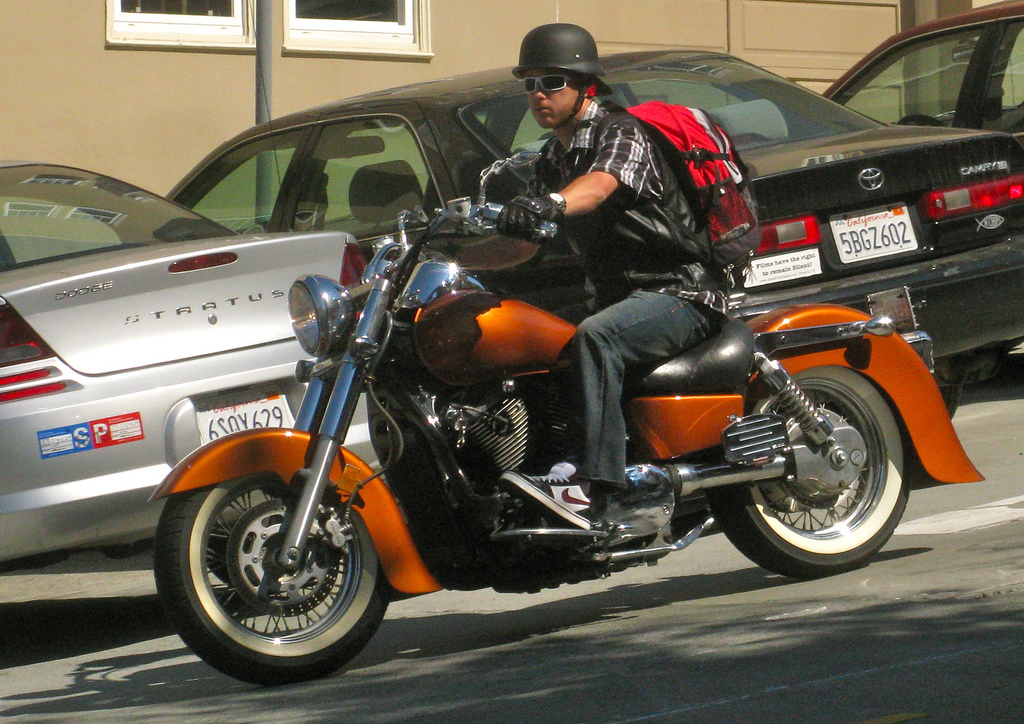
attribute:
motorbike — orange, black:
[143, 237, 979, 691]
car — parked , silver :
[11, 152, 373, 552]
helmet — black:
[506, 19, 609, 81]